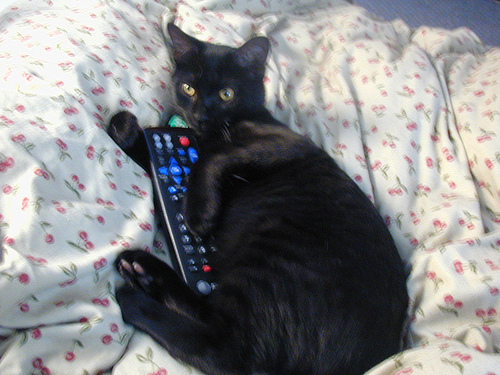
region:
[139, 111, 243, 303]
a very large remote control belongs to a very small cat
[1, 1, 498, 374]
cat is blurry, remote is blurry, blanket is blurry, green thing under remote is blurry too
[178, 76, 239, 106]
yellow gold eyes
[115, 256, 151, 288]
pinky-purply paw pads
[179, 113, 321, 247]
a lighter shoulder+foreleg than anything else. this may be sunshine, however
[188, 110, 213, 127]
the nose, it's black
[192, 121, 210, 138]
the mouth, it's black too, & almost entirely hidden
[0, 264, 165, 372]
blurry cherries on a wrinkly white ground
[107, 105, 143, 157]
right forepaw curled under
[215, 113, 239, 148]
only the beginning of cat's left whiskers are visible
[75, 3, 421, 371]
the cat is black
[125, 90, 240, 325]
remote control is black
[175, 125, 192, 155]
the button is red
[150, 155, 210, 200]
the buttons are blue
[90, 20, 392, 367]
cat is laying down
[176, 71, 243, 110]
cat's eyes are yellow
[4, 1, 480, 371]
red cherries on comforter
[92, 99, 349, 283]
cat is holding remote control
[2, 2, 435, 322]
cherries on blanket are red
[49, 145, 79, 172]
stems of cherries are green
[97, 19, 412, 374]
cat laying on print fabric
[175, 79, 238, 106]
green eyes on cat face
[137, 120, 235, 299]
remote control under cat paw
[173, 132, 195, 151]
red button on remote control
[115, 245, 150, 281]
pads on cat paw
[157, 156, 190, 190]
blue buttons on remote control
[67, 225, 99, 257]
red cherries on white material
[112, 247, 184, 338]
two back paws on cat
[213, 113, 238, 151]
whiskers on cat face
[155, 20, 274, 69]
ears on cat head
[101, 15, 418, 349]
the cat is laying down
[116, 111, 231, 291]
cat holding a remote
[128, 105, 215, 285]
the remote is black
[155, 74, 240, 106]
the cats eyes are yellow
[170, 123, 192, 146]
red power button on remote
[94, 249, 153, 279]
the cats paw is pink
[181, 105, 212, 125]
the nose is black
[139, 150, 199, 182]
blue buttons on the remote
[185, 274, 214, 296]
a grey button on the remote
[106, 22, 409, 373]
A cat with a remote.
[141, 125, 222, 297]
A remote control on a bed.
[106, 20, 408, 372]
A black cat on a bed.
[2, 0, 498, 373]
A blanket on a bed.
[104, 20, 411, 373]
A cat on a blanket.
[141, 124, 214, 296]
A remote control with buttons.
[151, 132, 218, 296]
Buttons on a remote control.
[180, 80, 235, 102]
Two green cat eyes.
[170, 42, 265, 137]
A cats head and face.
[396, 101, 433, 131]
Red cherries on a blanket.